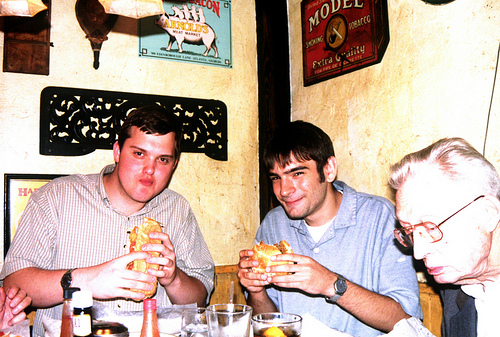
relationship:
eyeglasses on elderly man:
[392, 195, 489, 249] [384, 135, 499, 294]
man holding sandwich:
[237, 120, 423, 335] [252, 240, 294, 283]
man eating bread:
[0, 103, 216, 336] [122, 214, 165, 303]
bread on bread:
[138, 220, 157, 297] [122, 214, 165, 303]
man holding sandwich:
[5, 103, 216, 335] [251, 239, 295, 283]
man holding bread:
[237, 120, 423, 335] [122, 214, 165, 303]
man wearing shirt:
[237, 120, 423, 335] [239, 188, 414, 335]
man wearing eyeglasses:
[388, 140, 498, 333] [390, 195, 489, 246]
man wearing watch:
[5, 103, 216, 335] [56, 267, 79, 292]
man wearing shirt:
[5, 103, 216, 335] [22, 165, 217, 331]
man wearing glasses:
[384, 134, 498, 290] [387, 201, 462, 262]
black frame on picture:
[4, 172, 9, 259] [1, 2, 496, 334]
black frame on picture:
[2, 172, 70, 179] [1, 2, 496, 334]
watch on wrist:
[324, 272, 348, 304] [320, 262, 352, 302]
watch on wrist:
[56, 267, 74, 298] [57, 264, 88, 297]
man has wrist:
[5, 103, 216, 335] [57, 264, 88, 297]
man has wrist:
[237, 120, 423, 336] [320, 262, 352, 302]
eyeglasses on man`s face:
[392, 195, 489, 249] [397, 169, 498, 283]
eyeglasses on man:
[392, 195, 489, 249] [388, 140, 498, 333]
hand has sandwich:
[272, 242, 325, 288] [251, 239, 295, 283]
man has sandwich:
[237, 120, 423, 335] [251, 239, 295, 283]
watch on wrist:
[56, 267, 79, 292] [55, 267, 86, 298]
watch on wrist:
[330, 271, 345, 305] [317, 265, 344, 300]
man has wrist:
[237, 120, 423, 335] [317, 265, 344, 300]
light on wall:
[75, 0, 165, 68] [0, 0, 290, 309]